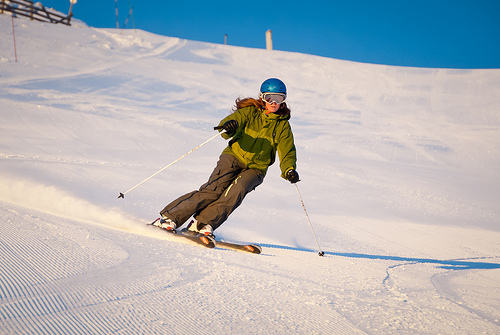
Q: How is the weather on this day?
A: It is clear.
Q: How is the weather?
A: It is clear.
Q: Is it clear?
A: Yes, it is clear.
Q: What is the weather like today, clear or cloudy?
A: It is clear.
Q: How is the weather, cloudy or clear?
A: It is clear.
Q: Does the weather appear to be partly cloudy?
A: No, it is clear.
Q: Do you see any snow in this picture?
A: Yes, there is snow.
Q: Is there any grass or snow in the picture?
A: Yes, there is snow.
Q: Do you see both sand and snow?
A: No, there is snow but no sand.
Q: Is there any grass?
A: No, there is no grass.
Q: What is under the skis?
A: The snow is under the skis.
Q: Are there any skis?
A: Yes, there are skis.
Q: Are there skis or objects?
A: Yes, there are skis.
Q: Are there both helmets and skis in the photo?
A: Yes, there are both skis and a helmet.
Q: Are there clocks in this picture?
A: No, there are no clocks.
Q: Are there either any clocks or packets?
A: No, there are no clocks or packets.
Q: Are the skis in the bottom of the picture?
A: Yes, the skis are in the bottom of the image.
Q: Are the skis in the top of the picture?
A: No, the skis are in the bottom of the image.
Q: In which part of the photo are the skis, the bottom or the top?
A: The skis are in the bottom of the image.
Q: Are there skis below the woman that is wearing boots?
A: Yes, there are skis below the woman.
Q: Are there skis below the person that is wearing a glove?
A: Yes, there are skis below the woman.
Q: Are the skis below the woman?
A: Yes, the skis are below the woman.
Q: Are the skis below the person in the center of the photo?
A: Yes, the skis are below the woman.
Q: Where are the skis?
A: The skis are in the snow.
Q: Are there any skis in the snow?
A: Yes, there are skis in the snow.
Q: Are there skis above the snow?
A: Yes, there are skis above the snow.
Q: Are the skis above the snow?
A: Yes, the skis are above the snow.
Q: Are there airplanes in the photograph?
A: No, there are no airplanes.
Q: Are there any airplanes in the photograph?
A: No, there are no airplanes.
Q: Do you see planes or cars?
A: No, there are no planes or cars.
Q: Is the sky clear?
A: Yes, the sky is clear.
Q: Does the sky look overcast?
A: No, the sky is clear.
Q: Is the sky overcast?
A: No, the sky is clear.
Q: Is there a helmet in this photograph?
A: Yes, there is a helmet.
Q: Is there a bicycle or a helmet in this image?
A: Yes, there is a helmet.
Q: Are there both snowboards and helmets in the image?
A: No, there is a helmet but no snowboards.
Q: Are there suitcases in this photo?
A: No, there are no suitcases.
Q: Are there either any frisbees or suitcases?
A: No, there are no suitcases or frisbees.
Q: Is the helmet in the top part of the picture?
A: Yes, the helmet is in the top of the image.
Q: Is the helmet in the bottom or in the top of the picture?
A: The helmet is in the top of the image.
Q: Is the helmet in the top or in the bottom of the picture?
A: The helmet is in the top of the image.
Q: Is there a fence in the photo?
A: Yes, there is a fence.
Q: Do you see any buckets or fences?
A: Yes, there is a fence.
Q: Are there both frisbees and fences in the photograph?
A: No, there is a fence but no frisbees.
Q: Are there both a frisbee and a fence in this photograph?
A: No, there is a fence but no frisbees.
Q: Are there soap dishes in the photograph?
A: No, there are no soap dishes.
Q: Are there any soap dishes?
A: No, there are no soap dishes.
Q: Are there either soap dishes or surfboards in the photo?
A: No, there are no soap dishes or surfboards.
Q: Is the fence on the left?
A: Yes, the fence is on the left of the image.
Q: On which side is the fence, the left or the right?
A: The fence is on the left of the image.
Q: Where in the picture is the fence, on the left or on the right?
A: The fence is on the left of the image.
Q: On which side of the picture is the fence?
A: The fence is on the left of the image.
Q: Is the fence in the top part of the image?
A: Yes, the fence is in the top of the image.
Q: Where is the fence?
A: The fence is on the snow.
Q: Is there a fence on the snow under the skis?
A: Yes, there is a fence on the snow.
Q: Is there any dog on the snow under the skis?
A: No, there is a fence on the snow.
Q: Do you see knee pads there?
A: No, there are no knee pads.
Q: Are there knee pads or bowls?
A: No, there are no knee pads or bowls.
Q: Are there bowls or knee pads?
A: No, there are no knee pads or bowls.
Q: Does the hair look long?
A: Yes, the hair is long.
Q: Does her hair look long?
A: Yes, the hair is long.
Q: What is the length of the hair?
A: The hair is long.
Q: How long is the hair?
A: The hair is long.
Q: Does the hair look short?
A: No, the hair is long.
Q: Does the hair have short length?
A: No, the hair is long.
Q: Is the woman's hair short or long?
A: The hair is long.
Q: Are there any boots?
A: Yes, there are boots.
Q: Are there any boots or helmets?
A: Yes, there are boots.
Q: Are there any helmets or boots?
A: Yes, there are boots.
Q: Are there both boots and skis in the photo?
A: Yes, there are both boots and skis.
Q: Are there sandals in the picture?
A: No, there are no sandals.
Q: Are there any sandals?
A: No, there are no sandals.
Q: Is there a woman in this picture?
A: Yes, there is a woman.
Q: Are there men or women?
A: Yes, there is a woman.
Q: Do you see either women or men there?
A: Yes, there is a woman.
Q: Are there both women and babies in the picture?
A: No, there is a woman but no babies.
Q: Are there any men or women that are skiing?
A: Yes, the woman is skiing.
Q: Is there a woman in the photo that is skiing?
A: Yes, there is a woman that is skiing.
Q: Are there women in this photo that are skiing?
A: Yes, there is a woman that is skiing.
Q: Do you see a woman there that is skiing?
A: Yes, there is a woman that is skiing.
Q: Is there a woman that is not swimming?
A: Yes, there is a woman that is skiing.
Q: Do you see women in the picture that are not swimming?
A: Yes, there is a woman that is skiing .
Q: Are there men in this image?
A: No, there are no men.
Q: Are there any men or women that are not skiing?
A: No, there is a woman but she is skiing.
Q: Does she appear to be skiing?
A: Yes, the woman is skiing.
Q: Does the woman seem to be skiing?
A: Yes, the woman is skiing.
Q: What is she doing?
A: The woman is skiing.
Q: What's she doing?
A: The woman is skiing.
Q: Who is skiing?
A: The woman is skiing.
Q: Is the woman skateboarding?
A: No, the woman is skiing.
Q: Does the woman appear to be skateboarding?
A: No, the woman is skiing.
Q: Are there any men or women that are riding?
A: No, there is a woman but she is skiing.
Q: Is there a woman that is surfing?
A: No, there is a woman but she is skiing.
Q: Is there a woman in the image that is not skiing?
A: No, there is a woman but she is skiing.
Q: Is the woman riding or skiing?
A: The woman is skiing.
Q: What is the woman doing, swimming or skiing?
A: The woman is skiing.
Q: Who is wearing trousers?
A: The woman is wearing trousers.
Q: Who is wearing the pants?
A: The woman is wearing trousers.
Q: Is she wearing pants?
A: Yes, the woman is wearing pants.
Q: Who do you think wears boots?
A: The woman wears boots.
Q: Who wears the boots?
A: The woman wears boots.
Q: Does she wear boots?
A: Yes, the woman wears boots.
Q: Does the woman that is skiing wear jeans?
A: No, the woman wears boots.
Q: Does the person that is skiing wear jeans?
A: No, the woman wears boots.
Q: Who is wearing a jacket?
A: The woman is wearing a jacket.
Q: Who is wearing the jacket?
A: The woman is wearing a jacket.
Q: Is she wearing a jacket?
A: Yes, the woman is wearing a jacket.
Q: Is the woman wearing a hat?
A: No, the woman is wearing a jacket.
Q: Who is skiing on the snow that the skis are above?
A: The woman is skiing on the snow.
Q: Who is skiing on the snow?
A: The woman is skiing on the snow.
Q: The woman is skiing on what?
A: The woman is skiing on the snow.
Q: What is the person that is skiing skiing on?
A: The woman is skiing on the snow.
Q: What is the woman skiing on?
A: The woman is skiing on the snow.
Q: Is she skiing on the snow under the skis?
A: Yes, the woman is skiing on the snow.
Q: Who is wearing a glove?
A: The woman is wearing a glove.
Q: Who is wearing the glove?
A: The woman is wearing a glove.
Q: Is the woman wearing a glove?
A: Yes, the woman is wearing a glove.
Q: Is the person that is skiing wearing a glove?
A: Yes, the woman is wearing a glove.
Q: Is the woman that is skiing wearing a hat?
A: No, the woman is wearing a glove.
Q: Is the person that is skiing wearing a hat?
A: No, the woman is wearing a glove.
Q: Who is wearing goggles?
A: The woman is wearing goggles.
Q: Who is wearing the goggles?
A: The woman is wearing goggles.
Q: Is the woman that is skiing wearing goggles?
A: Yes, the woman is wearing goggles.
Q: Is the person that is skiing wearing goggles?
A: Yes, the woman is wearing goggles.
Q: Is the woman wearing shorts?
A: No, the woman is wearing goggles.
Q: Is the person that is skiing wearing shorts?
A: No, the woman is wearing goggles.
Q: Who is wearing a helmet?
A: The woman is wearing a helmet.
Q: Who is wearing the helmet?
A: The woman is wearing a helmet.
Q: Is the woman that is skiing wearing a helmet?
A: Yes, the woman is wearing a helmet.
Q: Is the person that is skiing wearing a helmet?
A: Yes, the woman is wearing a helmet.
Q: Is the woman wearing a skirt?
A: No, the woman is wearing a helmet.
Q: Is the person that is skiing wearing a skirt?
A: No, the woman is wearing a helmet.